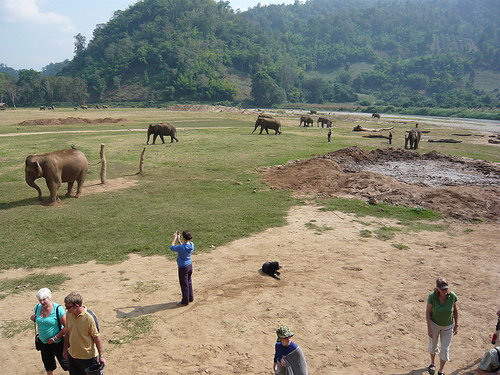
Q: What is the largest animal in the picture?
A: Elephant.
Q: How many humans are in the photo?
A: Seven.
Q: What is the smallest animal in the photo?
A: Dog.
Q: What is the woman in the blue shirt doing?
A: Taking a photo.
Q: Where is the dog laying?
A: In the dirt.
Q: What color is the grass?
A: Green.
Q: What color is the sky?
A: Blue.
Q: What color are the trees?
A: Green.